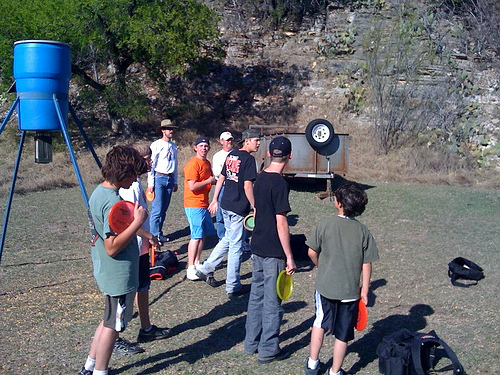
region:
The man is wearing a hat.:
[188, 136, 217, 148]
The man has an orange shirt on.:
[180, 155, 217, 198]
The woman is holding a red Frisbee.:
[99, 202, 149, 235]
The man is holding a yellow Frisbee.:
[264, 260, 301, 305]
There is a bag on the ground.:
[363, 317, 467, 373]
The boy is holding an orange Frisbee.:
[346, 292, 391, 344]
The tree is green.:
[78, 7, 211, 63]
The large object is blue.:
[3, 35, 82, 167]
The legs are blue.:
[42, 101, 103, 201]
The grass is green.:
[393, 187, 470, 218]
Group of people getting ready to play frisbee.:
[36, 55, 490, 371]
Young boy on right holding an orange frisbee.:
[306, 173, 383, 373]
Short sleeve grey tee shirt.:
[305, 202, 377, 305]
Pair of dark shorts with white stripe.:
[308, 281, 364, 351]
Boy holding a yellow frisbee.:
[235, 135, 301, 370]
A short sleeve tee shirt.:
[245, 161, 300, 261]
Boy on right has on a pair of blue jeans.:
[240, 245, 290, 370]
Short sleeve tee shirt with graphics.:
[214, 142, 257, 217]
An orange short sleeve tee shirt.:
[177, 148, 215, 214]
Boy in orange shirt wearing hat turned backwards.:
[182, 130, 224, 294]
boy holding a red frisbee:
[84, 160, 164, 272]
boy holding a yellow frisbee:
[260, 142, 304, 349]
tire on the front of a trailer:
[306, 123, 353, 148]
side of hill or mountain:
[241, 16, 491, 162]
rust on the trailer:
[286, 130, 354, 180]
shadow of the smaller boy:
[317, 220, 448, 372]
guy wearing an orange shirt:
[193, 138, 208, 205]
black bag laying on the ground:
[438, 248, 498, 286]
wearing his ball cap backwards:
[235, 132, 270, 145]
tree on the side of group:
[88, 1, 195, 136]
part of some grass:
[391, 224, 429, 274]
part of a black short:
[326, 305, 351, 329]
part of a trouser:
[251, 307, 269, 348]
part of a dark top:
[261, 207, 275, 237]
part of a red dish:
[111, 213, 127, 225]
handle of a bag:
[407, 345, 427, 366]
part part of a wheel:
[300, 102, 330, 143]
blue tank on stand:
[13, 39, 70, 162]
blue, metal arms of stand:
[2, 94, 108, 279]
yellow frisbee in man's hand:
[276, 269, 292, 302]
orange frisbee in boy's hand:
[356, 299, 367, 333]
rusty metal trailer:
[245, 119, 350, 197]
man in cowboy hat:
[145, 119, 179, 242]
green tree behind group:
[0, 0, 221, 135]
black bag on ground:
[448, 256, 484, 288]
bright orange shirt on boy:
[182, 156, 210, 207]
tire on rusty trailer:
[306, 119, 336, 149]